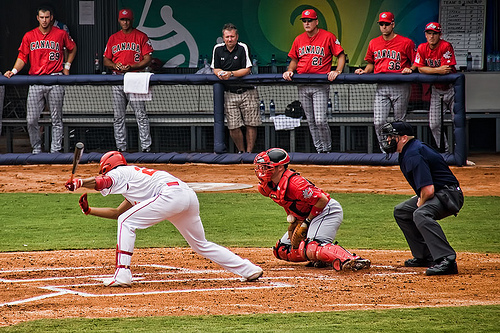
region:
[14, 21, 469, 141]
people watching the baseball game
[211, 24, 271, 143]
a man in a black shirt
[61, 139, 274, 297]
a baseball player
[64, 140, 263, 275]
a man swinging a bat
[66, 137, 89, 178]
a baseball bat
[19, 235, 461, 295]
sand on the baseball field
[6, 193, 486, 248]
grass on the baseball field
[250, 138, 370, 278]
a catcher of the baseball game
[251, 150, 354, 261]
a person wearing a red mask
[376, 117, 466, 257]
the umpire of the game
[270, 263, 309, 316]
part of a ground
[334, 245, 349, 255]
part og a guard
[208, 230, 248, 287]
part fo a leg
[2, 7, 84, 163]
The man is wearing a baseball uniform.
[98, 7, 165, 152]
The man is wearing a baseball uniform.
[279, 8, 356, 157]
The man is wearing a baseball uniform.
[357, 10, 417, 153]
The man is wearing a baseball uniform.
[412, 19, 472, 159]
The man is wearing a baseball uniform.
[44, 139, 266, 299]
The man is wearing a baseball uniform.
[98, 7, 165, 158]
The man is wearing a baseball cap.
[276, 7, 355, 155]
The man is wearing a baseball cap.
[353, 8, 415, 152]
The man is wearing a baseball cap.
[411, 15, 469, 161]
The man is wearing a baseball cap.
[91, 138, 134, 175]
head of a person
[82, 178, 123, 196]
arm of a person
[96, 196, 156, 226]
arm of a person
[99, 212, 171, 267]
leg of a person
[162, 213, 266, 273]
leg of a person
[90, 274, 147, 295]
feet of a person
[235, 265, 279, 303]
feet of a person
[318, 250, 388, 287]
feet of a person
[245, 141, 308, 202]
head of a person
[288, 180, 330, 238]
arm of a person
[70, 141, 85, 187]
A baseball bat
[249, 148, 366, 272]
The catcher on the baseball field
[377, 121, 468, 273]
An umpire in all black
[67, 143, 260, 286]
A baseball player wearing white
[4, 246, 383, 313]
Home base on the baseball field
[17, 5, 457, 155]
Player standing by and watching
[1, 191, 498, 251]
Grass on the field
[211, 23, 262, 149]
A coach standing by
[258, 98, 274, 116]
Two bottles of water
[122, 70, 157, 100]
A white towel